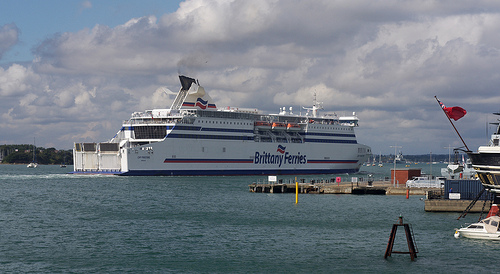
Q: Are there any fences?
A: No, there are no fences.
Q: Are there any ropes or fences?
A: No, there are no fences or ropes.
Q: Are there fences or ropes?
A: No, there are no fences or ropes.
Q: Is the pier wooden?
A: Yes, the pier is wooden.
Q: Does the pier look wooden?
A: Yes, the pier is wooden.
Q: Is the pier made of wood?
A: Yes, the pier is made of wood.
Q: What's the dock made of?
A: The dock is made of wood.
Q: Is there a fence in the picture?
A: No, there are no fences.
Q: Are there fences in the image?
A: No, there are no fences.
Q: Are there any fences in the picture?
A: No, there are no fences.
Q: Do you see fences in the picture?
A: No, there are no fences.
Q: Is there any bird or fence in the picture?
A: No, there are no fences or birds.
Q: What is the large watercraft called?
A: The watercraft is a ship.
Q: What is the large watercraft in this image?
A: The watercraft is a ship.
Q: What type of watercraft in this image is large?
A: The watercraft is a ship.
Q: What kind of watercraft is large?
A: The watercraft is a ship.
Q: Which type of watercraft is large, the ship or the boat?
A: The ship is large.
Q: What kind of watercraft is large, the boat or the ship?
A: The ship is large.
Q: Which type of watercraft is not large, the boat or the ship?
A: The boat is not large.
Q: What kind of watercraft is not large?
A: The watercraft is a boat.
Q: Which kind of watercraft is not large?
A: The watercraft is a boat.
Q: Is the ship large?
A: Yes, the ship is large.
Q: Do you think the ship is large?
A: Yes, the ship is large.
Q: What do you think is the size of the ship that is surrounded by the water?
A: The ship is large.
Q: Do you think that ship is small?
A: No, the ship is large.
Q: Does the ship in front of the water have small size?
A: No, the ship is large.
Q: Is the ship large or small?
A: The ship is large.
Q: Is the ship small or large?
A: The ship is large.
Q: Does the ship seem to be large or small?
A: The ship is large.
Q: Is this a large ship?
A: Yes, this is a large ship.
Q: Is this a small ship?
A: No, this is a large ship.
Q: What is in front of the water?
A: The ship is in front of the water.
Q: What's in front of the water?
A: The ship is in front of the water.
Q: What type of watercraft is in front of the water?
A: The watercraft is a ship.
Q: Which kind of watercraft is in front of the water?
A: The watercraft is a ship.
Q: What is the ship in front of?
A: The ship is in front of the water.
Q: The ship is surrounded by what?
A: The ship is surrounded by the water.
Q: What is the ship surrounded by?
A: The ship is surrounded by the water.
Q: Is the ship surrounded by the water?
A: Yes, the ship is surrounded by the water.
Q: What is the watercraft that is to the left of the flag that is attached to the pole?
A: The watercraft is a ship.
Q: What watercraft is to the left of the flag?
A: The watercraft is a ship.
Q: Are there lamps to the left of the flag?
A: No, there is a ship to the left of the flag.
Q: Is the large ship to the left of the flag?
A: Yes, the ship is to the left of the flag.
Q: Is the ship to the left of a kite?
A: No, the ship is to the left of the flag.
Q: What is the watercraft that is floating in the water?
A: The watercraft is a ship.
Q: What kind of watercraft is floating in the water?
A: The watercraft is a ship.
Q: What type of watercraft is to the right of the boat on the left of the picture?
A: The watercraft is a ship.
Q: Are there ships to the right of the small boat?
A: Yes, there is a ship to the right of the boat.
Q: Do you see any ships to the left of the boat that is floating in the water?
A: No, the ship is to the right of the boat.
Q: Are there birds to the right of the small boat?
A: No, there is a ship to the right of the boat.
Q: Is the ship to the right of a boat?
A: Yes, the ship is to the right of a boat.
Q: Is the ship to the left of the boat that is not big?
A: No, the ship is to the right of the boat.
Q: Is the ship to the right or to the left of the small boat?
A: The ship is to the right of the boat.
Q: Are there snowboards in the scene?
A: No, there are no snowboards.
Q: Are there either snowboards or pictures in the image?
A: No, there are no snowboards or pictures.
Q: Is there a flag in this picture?
A: Yes, there is a flag.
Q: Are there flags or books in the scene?
A: Yes, there is a flag.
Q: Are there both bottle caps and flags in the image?
A: No, there is a flag but no bottle caps.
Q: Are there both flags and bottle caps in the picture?
A: No, there is a flag but no bottle caps.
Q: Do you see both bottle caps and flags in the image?
A: No, there is a flag but no bottle caps.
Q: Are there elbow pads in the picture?
A: No, there are no elbow pads.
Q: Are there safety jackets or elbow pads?
A: No, there are no elbow pads or safety jackets.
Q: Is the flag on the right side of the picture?
A: Yes, the flag is on the right of the image.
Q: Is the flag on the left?
A: No, the flag is on the right of the image.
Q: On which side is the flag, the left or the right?
A: The flag is on the right of the image.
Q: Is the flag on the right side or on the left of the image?
A: The flag is on the right of the image.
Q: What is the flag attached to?
A: The flag is attached to the pole.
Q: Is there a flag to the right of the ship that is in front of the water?
A: Yes, there is a flag to the right of the ship.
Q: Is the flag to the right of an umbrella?
A: No, the flag is to the right of the ship.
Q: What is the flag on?
A: The flag is on the pole.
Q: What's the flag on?
A: The flag is on the pole.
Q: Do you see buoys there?
A: Yes, there is a buoy.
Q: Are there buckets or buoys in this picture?
A: Yes, there is a buoy.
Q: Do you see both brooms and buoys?
A: No, there is a buoy but no brooms.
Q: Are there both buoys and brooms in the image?
A: No, there is a buoy but no brooms.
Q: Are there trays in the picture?
A: No, there are no trays.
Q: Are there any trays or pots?
A: No, there are no trays or pots.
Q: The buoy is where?
A: The buoy is in the water.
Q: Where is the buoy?
A: The buoy is in the water.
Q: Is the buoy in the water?
A: Yes, the buoy is in the water.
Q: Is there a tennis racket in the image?
A: No, there are no rackets.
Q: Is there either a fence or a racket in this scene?
A: No, there are no rackets or fences.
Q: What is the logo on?
A: The logo is on the ship.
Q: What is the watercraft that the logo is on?
A: The watercraft is a ship.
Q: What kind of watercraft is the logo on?
A: The logo is on the ship.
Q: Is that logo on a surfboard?
A: No, the logo is on the ship.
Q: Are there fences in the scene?
A: No, there are no fences.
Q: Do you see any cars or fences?
A: No, there are no fences or cars.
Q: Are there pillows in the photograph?
A: No, there are no pillows.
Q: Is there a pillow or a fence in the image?
A: No, there are no pillows or fences.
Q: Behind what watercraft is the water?
A: The water is behind the ship.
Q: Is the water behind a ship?
A: Yes, the water is behind a ship.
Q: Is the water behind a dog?
A: No, the water is behind a ship.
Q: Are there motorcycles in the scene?
A: No, there are no motorcycles.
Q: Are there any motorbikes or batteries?
A: No, there are no motorbikes or batteries.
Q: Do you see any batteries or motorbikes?
A: No, there are no motorbikes or batteries.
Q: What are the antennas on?
A: The antennas are on the ship.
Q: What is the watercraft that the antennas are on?
A: The watercraft is a ship.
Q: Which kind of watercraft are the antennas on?
A: The antennas are on the ship.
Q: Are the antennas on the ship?
A: Yes, the antennas are on the ship.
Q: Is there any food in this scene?
A: No, there is no food.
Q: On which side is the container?
A: The container is on the right of the image.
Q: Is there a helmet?
A: No, there are no helmets.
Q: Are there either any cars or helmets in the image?
A: No, there are no helmets or cars.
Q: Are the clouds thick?
A: Yes, the clouds are thick.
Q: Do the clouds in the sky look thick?
A: Yes, the clouds are thick.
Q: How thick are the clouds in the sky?
A: The clouds are thick.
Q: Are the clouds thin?
A: No, the clouds are thick.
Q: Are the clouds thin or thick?
A: The clouds are thick.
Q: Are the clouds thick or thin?
A: The clouds are thick.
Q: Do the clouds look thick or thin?
A: The clouds are thick.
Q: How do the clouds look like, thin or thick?
A: The clouds are thick.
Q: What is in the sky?
A: The clouds are in the sky.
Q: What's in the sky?
A: The clouds are in the sky.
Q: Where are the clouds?
A: The clouds are in the sky.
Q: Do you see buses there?
A: No, there are no buses.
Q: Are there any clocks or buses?
A: No, there are no buses or clocks.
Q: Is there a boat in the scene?
A: Yes, there is a boat.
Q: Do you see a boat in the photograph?
A: Yes, there is a boat.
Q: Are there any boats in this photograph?
A: Yes, there is a boat.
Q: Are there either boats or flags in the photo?
A: Yes, there is a boat.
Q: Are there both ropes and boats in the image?
A: No, there is a boat but no ropes.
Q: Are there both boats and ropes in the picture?
A: No, there is a boat but no ropes.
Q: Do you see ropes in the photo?
A: No, there are no ropes.